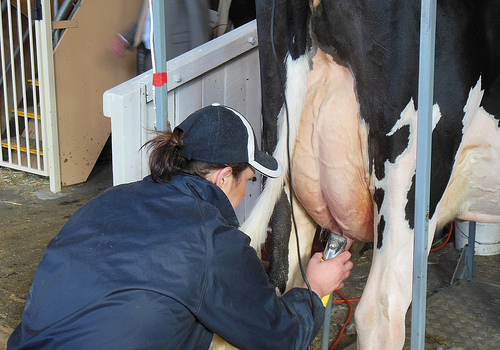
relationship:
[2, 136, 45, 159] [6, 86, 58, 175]
yellow stripe on stair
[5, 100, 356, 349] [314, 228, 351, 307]
woman holding device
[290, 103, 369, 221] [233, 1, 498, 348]
glands on cow